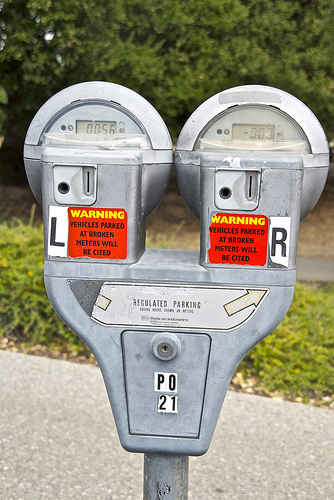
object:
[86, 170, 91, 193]
slot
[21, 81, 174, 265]
parking meter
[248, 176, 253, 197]
slot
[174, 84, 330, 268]
parking meter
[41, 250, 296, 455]
container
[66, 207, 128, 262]
sticker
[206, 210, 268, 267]
sticker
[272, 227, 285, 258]
r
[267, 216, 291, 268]
sticker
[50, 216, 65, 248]
l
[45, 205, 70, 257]
sticker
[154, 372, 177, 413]
sticker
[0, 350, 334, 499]
concrete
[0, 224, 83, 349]
grass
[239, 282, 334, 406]
grass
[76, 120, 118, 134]
display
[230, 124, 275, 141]
display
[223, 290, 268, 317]
arrow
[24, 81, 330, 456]
double meter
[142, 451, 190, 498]
pole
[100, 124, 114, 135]
time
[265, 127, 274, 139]
time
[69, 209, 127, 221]
word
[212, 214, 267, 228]
word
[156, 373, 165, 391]
letter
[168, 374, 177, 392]
letter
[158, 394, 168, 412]
number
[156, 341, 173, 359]
key hole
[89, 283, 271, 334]
sign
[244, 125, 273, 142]
digits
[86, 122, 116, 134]
digits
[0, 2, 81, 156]
trees